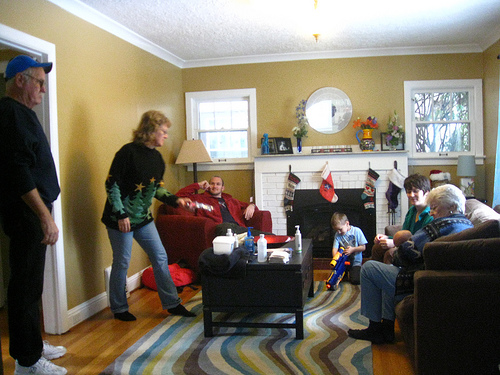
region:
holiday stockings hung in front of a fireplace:
[259, 159, 401, 259]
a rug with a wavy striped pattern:
[109, 276, 369, 374]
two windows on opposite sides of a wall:
[182, 78, 490, 167]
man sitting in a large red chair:
[156, 176, 269, 266]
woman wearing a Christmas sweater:
[102, 140, 179, 232]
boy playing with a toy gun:
[318, 213, 364, 291]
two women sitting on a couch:
[358, 171, 499, 365]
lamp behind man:
[176, 136, 223, 216]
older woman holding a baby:
[389, 183, 469, 258]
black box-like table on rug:
[202, 234, 318, 349]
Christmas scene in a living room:
[5, 0, 486, 361]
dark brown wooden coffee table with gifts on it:
[199, 223, 323, 350]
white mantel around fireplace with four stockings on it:
[250, 149, 404, 230]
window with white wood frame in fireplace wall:
[176, 83, 264, 172]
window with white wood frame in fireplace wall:
[400, 75, 485, 167]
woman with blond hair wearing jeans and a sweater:
[88, 100, 200, 327]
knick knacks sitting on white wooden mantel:
[254, 117, 404, 157]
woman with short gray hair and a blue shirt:
[337, 179, 479, 343]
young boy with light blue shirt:
[311, 210, 371, 290]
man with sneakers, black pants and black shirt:
[3, 45, 86, 372]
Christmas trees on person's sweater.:
[113, 182, 173, 244]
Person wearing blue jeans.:
[93, 225, 170, 301]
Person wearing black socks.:
[106, 295, 218, 337]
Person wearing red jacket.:
[192, 178, 248, 227]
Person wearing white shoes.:
[34, 334, 83, 366]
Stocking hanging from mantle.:
[276, 150, 317, 230]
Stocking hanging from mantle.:
[312, 148, 342, 231]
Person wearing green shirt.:
[399, 195, 421, 228]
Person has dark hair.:
[396, 170, 424, 194]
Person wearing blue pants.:
[354, 266, 386, 330]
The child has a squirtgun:
[311, 213, 362, 295]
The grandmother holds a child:
[349, 190, 462, 317]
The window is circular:
[308, 89, 350, 136]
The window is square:
[401, 73, 491, 161]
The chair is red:
[167, 198, 260, 258]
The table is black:
[197, 249, 307, 326]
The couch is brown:
[416, 240, 483, 355]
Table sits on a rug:
[127, 288, 372, 368]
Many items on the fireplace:
[262, 118, 407, 168]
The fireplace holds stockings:
[249, 135, 413, 272]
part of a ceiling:
[246, 0, 290, 37]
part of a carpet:
[220, 328, 243, 360]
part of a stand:
[286, 310, 305, 348]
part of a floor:
[107, 310, 141, 342]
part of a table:
[247, 269, 285, 314]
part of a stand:
[288, 308, 303, 335]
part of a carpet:
[169, 323, 190, 362]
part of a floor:
[94, 324, 116, 352]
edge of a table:
[283, 285, 303, 332]